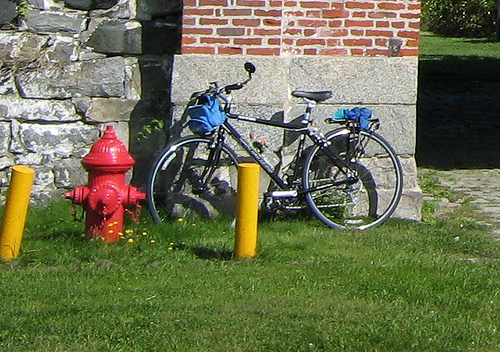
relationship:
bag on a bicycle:
[183, 90, 226, 140] [148, 63, 408, 226]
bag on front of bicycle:
[183, 90, 226, 140] [148, 63, 408, 226]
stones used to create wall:
[0, 0, 135, 194] [2, 1, 416, 222]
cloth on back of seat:
[332, 105, 372, 131] [288, 91, 333, 107]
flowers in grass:
[108, 221, 175, 253] [247, 266, 374, 311]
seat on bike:
[275, 79, 350, 111] [168, 87, 418, 218]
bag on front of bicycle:
[183, 90, 227, 136] [148, 62, 403, 232]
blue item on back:
[336, 105, 371, 128] [318, 100, 388, 130]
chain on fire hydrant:
[99, 205, 109, 231] [61, 122, 147, 245]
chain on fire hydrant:
[125, 203, 142, 224] [61, 122, 147, 245]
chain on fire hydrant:
[65, 200, 85, 222] [61, 122, 147, 245]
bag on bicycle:
[183, 90, 227, 136] [148, 63, 408, 226]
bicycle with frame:
[148, 63, 408, 226] [195, 105, 371, 204]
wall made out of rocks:
[176, 3, 428, 223] [4, 11, 134, 133]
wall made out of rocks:
[0, 2, 141, 199] [4, 11, 134, 133]